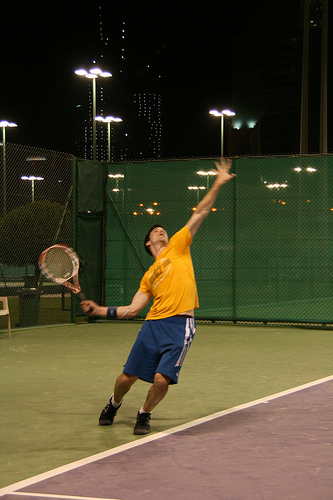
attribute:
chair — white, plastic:
[0, 291, 13, 340]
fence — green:
[0, 142, 333, 331]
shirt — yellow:
[140, 225, 203, 322]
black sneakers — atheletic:
[88, 394, 156, 438]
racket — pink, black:
[22, 230, 108, 335]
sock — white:
[107, 392, 124, 413]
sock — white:
[136, 404, 153, 416]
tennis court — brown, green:
[4, 320, 322, 498]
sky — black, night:
[196, 45, 268, 104]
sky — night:
[1, 0, 332, 157]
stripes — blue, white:
[175, 314, 195, 371]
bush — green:
[0, 198, 91, 259]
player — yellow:
[122, 198, 261, 340]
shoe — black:
[131, 411, 152, 436]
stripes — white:
[165, 314, 204, 384]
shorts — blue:
[119, 300, 206, 396]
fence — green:
[67, 157, 326, 323]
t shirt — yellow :
[135, 225, 202, 322]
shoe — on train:
[131, 405, 156, 446]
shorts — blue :
[112, 320, 211, 382]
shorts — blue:
[118, 311, 196, 387]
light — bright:
[74, 90, 145, 162]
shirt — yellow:
[137, 221, 203, 319]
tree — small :
[1, 202, 73, 280]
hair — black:
[144, 221, 165, 258]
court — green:
[5, 310, 331, 498]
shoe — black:
[97, 398, 123, 430]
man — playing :
[80, 156, 236, 433]